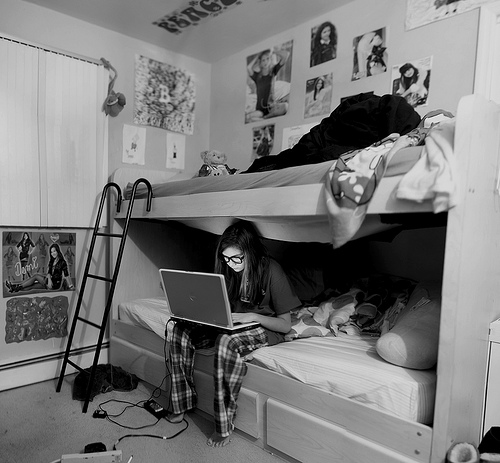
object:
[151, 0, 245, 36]
poster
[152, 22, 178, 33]
word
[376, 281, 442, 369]
pillow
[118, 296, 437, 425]
bedcovers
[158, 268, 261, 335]
laptop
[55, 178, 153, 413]
ladder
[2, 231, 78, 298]
pictures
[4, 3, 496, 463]
room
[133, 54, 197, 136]
poster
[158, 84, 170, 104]
letter b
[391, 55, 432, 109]
poster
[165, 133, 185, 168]
poster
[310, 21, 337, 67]
poster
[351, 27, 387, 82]
poster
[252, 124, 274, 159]
poster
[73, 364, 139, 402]
towel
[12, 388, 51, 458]
floor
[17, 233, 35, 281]
women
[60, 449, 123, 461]
power strip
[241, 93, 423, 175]
cloth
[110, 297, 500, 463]
bed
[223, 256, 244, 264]
eyeglasses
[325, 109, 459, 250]
blankets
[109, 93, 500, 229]
bed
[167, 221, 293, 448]
girl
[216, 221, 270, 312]
hair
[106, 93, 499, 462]
bunk bed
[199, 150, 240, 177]
teddy bear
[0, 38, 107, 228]
vertical blinds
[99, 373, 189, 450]
cord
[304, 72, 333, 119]
posters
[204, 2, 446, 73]
wall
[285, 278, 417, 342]
blankets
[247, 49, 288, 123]
woman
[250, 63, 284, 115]
leotard